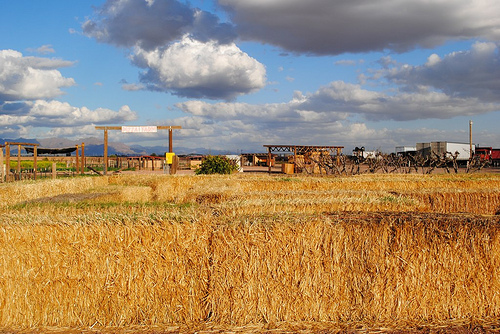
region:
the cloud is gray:
[131, 13, 151, 33]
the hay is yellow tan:
[133, 265, 165, 298]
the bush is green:
[208, 159, 226, 168]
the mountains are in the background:
[84, 137, 103, 154]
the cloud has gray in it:
[465, 74, 484, 92]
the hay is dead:
[283, 188, 311, 206]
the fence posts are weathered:
[332, 163, 363, 174]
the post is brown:
[265, 152, 273, 168]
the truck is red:
[477, 148, 495, 160]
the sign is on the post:
[123, 126, 153, 133]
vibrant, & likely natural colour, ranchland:
[0, 1, 499, 331]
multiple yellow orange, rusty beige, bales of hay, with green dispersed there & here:
[0, 175, 499, 332]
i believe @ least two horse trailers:
[393, 136, 474, 166]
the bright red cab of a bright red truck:
[469, 141, 499, 166]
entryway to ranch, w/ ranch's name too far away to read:
[97, 119, 190, 176]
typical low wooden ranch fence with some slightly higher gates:
[2, 138, 185, 183]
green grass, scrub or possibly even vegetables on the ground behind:
[0, 158, 140, 178]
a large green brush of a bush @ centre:
[192, 153, 244, 177]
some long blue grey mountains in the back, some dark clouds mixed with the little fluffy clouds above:
[0, 130, 295, 160]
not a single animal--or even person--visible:
[4, 134, 499, 200]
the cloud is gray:
[293, 22, 325, 43]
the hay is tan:
[243, 248, 296, 272]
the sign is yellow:
[166, 152, 173, 164]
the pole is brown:
[167, 137, 173, 147]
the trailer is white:
[451, 144, 464, 155]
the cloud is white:
[182, 48, 210, 65]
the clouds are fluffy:
[13, 68, 44, 93]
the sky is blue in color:
[20, 15, 47, 37]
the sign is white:
[126, 126, 148, 133]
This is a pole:
[151, 110, 188, 176]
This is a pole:
[97, 116, 124, 193]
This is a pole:
[78, 135, 94, 179]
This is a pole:
[74, 139, 83, 182]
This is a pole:
[30, 133, 42, 189]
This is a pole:
[14, 133, 24, 189]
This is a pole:
[3, 132, 13, 192]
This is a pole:
[263, 137, 282, 187]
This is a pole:
[288, 135, 308, 187]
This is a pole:
[333, 137, 348, 187]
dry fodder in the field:
[231, 220, 390, 302]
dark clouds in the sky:
[111, 0, 181, 42]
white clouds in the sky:
[37, 73, 62, 95]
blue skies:
[13, 5, 60, 35]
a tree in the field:
[200, 152, 235, 173]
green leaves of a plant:
[211, 158, 228, 165]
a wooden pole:
[101, 131, 111, 173]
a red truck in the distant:
[478, 146, 499, 161]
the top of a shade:
[263, 140, 343, 150]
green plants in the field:
[36, 161, 63, 166]